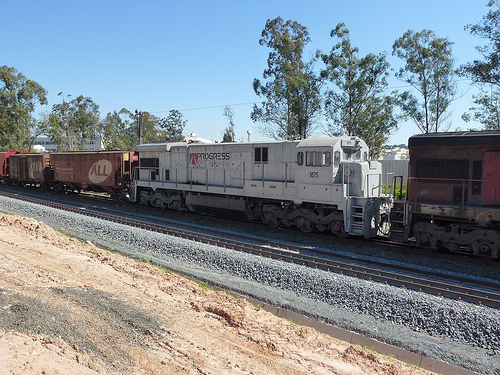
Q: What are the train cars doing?
A: Traveling down the track.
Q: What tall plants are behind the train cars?
A: Pine trees.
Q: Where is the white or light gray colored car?
A: In the middle.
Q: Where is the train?
A: On train tracks.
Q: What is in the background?
A: Trees and sky.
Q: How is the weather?
A: Clear.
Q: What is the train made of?
A: Metal.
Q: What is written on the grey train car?
A: PROGRESS.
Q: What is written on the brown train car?
A: ALL.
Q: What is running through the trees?
A: Telephone line.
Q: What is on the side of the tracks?
A: Gravel.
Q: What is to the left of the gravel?
A: Dirt.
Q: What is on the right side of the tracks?
A: Trees.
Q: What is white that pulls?
A: Engine.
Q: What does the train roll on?
A: Tracks.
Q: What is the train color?
A: Grey.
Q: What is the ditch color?
A: Grey.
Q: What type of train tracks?
A: Rusty.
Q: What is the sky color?
A: Blue.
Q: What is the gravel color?
A: Brown.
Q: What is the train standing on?
A: Tracks.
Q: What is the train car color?
A: White.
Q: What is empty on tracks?
A: Section.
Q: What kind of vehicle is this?
A: A train.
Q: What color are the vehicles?
A: Red and white.